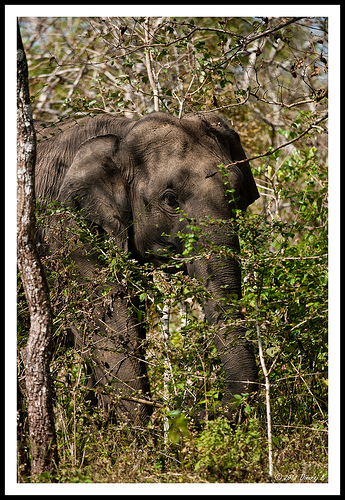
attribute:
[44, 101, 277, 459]
elephant — alone, gray, grey, big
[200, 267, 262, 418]
trunk — long, large, grey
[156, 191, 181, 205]
eye — black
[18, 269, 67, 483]
tree trunk — brown, skinny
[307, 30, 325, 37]
sky — blue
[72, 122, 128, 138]
skin — grey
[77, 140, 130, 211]
ears — big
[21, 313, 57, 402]
stem — brown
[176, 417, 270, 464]
bushes — green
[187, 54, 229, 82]
leaves — green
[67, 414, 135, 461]
bush — green